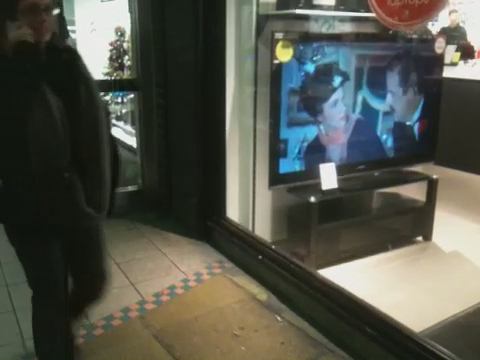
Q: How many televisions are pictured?
A: One.